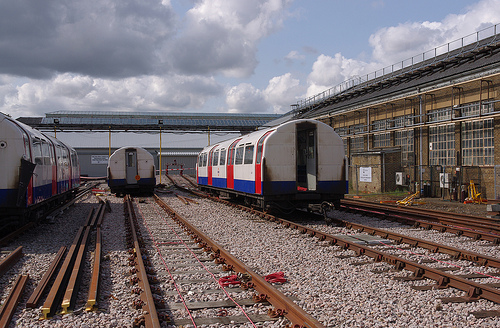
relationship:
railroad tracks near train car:
[312, 212, 498, 318] [196, 116, 352, 214]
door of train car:
[306, 128, 316, 191] [196, 116, 352, 214]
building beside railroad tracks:
[276, 27, 499, 202] [312, 212, 498, 318]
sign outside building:
[356, 162, 372, 184] [276, 27, 499, 202]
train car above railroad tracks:
[196, 116, 352, 214] [312, 212, 498, 318]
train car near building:
[196, 116, 352, 214] [276, 27, 499, 202]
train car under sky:
[196, 116, 352, 214] [2, 2, 499, 113]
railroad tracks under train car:
[312, 212, 498, 318] [196, 116, 352, 214]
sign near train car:
[356, 162, 372, 184] [196, 116, 352, 214]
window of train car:
[243, 144, 254, 165] [196, 116, 352, 214]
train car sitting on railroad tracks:
[196, 116, 352, 214] [312, 212, 498, 318]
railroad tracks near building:
[312, 212, 498, 318] [276, 27, 499, 202]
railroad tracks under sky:
[312, 212, 498, 318] [2, 2, 499, 113]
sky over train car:
[2, 2, 499, 113] [196, 116, 352, 214]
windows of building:
[333, 95, 496, 172] [276, 27, 499, 202]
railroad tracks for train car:
[312, 212, 498, 318] [196, 116, 352, 214]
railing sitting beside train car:
[17, 170, 117, 326] [196, 116, 352, 214]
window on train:
[243, 144, 254, 165] [184, 104, 363, 224]